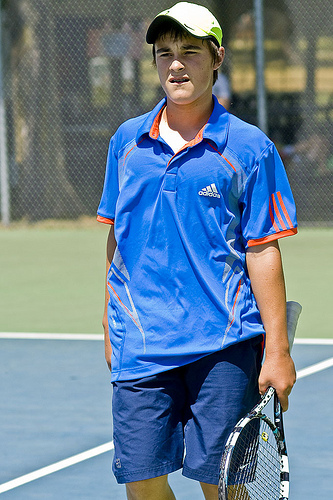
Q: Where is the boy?
A: Tennis court.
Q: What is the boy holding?
A: Tennis racket.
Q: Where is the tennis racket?
A: In the boy's hand.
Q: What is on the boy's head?
A: A hat.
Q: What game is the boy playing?
A: Tennis.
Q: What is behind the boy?
A: A fence.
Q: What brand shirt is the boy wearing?
A: Adidas.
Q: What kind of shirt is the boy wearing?
A: Collar shirt.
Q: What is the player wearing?
A: Blue and orange shirt.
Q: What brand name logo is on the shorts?
A: Nike.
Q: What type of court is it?
A: Tennis.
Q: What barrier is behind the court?
A: Chain link fence.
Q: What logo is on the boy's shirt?
A: Adidas.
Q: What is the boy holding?
A: Tennis racket.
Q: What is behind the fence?
A: Tree.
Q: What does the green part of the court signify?
A: Out of bounds.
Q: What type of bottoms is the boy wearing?
A: Shorts.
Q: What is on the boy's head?
A: Hat.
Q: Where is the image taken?
A: Tennis court.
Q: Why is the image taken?
A: Remembrance.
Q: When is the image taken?
A: Not playing.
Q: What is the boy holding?
A: Racket.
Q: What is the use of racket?
A: Play tennis.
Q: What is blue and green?
A: Court.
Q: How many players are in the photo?
A: One.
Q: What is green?
A: Hat.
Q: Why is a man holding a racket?
A: To play tennis.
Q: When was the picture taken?
A: Daytime.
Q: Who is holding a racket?
A: Tennis player.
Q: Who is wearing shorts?
A: The tennis player.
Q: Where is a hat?
A: On player's head.